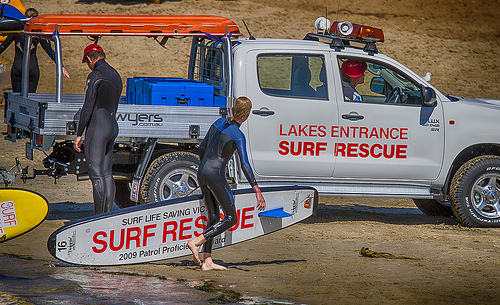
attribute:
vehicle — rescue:
[30, 23, 482, 247]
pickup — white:
[19, 39, 484, 190]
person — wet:
[198, 71, 281, 261]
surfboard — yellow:
[3, 169, 51, 248]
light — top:
[318, 13, 387, 41]